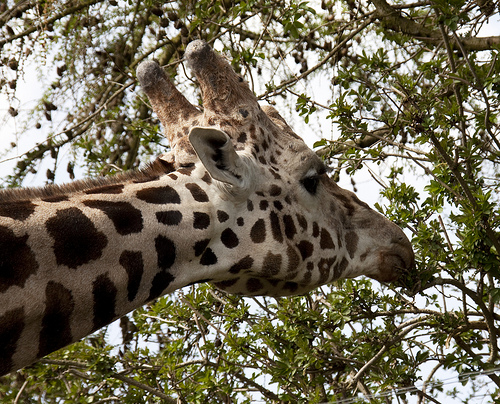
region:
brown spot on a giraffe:
[131, 181, 183, 206]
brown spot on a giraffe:
[147, 203, 188, 228]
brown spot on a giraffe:
[152, 229, 179, 272]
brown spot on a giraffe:
[143, 265, 179, 305]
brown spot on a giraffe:
[117, 243, 154, 306]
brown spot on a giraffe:
[87, 267, 125, 334]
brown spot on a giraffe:
[33, 270, 74, 362]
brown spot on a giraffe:
[37, 199, 109, 276]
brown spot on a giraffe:
[38, 188, 72, 209]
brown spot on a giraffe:
[0, 214, 40, 306]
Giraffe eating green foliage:
[0, 39, 419, 371]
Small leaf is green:
[338, 316, 345, 328]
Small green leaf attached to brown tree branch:
[311, 135, 326, 147]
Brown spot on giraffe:
[81, 196, 144, 234]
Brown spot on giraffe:
[152, 207, 183, 228]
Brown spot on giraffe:
[132, 184, 185, 209]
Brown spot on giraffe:
[246, 212, 271, 240]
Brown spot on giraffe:
[344, 225, 359, 259]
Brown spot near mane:
[0, 200, 37, 221]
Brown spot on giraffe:
[118, 247, 148, 306]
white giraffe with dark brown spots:
[1, 45, 426, 389]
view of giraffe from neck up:
[0, 33, 427, 402]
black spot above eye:
[312, 158, 329, 179]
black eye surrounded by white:
[291, 162, 323, 202]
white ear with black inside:
[190, 127, 244, 182]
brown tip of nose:
[382, 222, 414, 284]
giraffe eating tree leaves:
[337, 197, 429, 292]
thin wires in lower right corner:
[308, 366, 499, 401]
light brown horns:
[120, 40, 256, 124]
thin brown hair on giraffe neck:
[0, 159, 187, 200]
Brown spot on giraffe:
[43, 204, 112, 269]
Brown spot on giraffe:
[0, 226, 40, 297]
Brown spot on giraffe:
[41, 275, 76, 350]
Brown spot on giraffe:
[320, 226, 337, 253]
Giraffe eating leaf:
[0, 40, 417, 387]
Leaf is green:
[428, 185, 445, 199]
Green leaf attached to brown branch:
[312, 135, 326, 152]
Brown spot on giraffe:
[258, 249, 283, 277]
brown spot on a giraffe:
[231, 210, 245, 230]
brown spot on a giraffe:
[265, 178, 286, 200]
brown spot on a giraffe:
[245, 215, 267, 245]